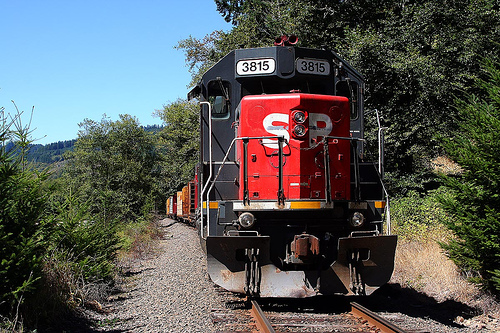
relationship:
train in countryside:
[164, 33, 398, 299] [2, 2, 498, 331]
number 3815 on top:
[298, 55, 330, 72] [234, 49, 333, 74]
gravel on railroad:
[81, 215, 476, 330] [246, 297, 404, 331]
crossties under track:
[164, 205, 419, 329] [103, 288, 449, 330]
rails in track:
[231, 298, 394, 326] [227, 292, 434, 331]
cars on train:
[157, 172, 211, 228] [163, 30, 399, 305]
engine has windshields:
[187, 32, 399, 297] [211, 80, 358, 119]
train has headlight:
[163, 30, 399, 305] [235, 207, 368, 227]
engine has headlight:
[187, 32, 399, 297] [352, 214, 365, 226]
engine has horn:
[187, 32, 399, 297] [274, 36, 299, 46]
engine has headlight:
[190, 29, 401, 317] [290, 103, 312, 126]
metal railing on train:
[221, 128, 369, 216] [163, 30, 399, 305]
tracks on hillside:
[228, 293, 401, 329] [37, 207, 497, 327]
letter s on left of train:
[261, 107, 299, 154] [163, 30, 399, 305]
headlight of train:
[235, 210, 255, 227] [163, 30, 399, 305]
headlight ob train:
[352, 211, 364, 225] [163, 30, 399, 305]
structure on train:
[236, 92, 366, 202] [183, 40, 405, 297]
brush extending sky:
[354, 104, 396, 224] [86, 18, 186, 68]